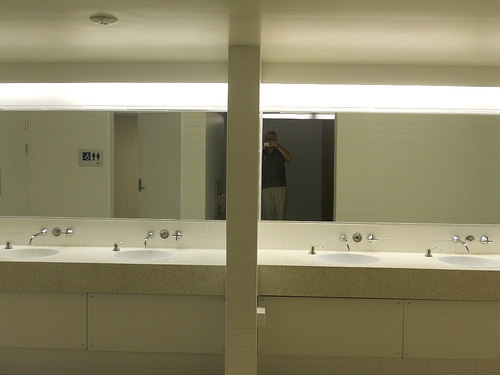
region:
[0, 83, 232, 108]
lighting in the bathroom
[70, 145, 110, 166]
sign identifying male or female bathroom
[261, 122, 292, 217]
man taking picture in mirror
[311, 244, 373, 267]
sink in the bathroom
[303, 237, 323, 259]
soap dispenser in bathroom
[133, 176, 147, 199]
handle for the bathroom door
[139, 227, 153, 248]
water faucet above sink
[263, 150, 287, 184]
man wearing black shirt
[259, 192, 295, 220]
man wearing grey pants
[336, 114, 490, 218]
white walls in the bathroom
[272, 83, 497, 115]
white lights over sink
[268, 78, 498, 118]
white light above the morror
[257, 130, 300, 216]
a person in the mirror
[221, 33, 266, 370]
a divider between the mirror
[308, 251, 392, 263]
a white round sink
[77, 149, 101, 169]
a sign on the wall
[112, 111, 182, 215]
a open door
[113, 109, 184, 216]
a white open door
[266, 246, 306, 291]
a white top on a sink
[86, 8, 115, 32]
a water sprinkle in the ceiling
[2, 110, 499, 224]
mirror above the sinks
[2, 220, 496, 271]
four white sinks in a row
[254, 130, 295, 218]
reflection of person taking the picture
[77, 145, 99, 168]
reflection of white and black sign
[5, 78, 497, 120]
light above the mirror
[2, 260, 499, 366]
counter sinks are in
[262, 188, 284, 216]
pants of person taking photo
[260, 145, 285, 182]
shirt of person taking the photo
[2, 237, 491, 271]
four sink basins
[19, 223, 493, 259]
knobs and faucets of the sinks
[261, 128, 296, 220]
Man's reflection in the mirror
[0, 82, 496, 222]
Mirror on the wall in the comfort room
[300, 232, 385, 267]
Sink on the wall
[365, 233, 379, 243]
Silver tap on the wall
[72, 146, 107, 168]
comfort room sign on the wall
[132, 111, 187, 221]
White door of the toilet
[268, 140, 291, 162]
Left arm of the man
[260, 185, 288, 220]
Pants worn by the man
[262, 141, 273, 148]
Cell phone held by the man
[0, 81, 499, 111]
Toilet light on the ceiling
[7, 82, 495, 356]
sinks in a public restroom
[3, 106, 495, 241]
a large mirror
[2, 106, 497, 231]
a mirror in a public restroom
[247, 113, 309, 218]
this person is taking the photo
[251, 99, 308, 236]
the reflection of a person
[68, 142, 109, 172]
a bathroom sign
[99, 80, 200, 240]
a door to the bathroom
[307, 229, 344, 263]
the metal soap dispenser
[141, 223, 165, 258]
the sink faucet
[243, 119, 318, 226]
he is taking a photo with his phone